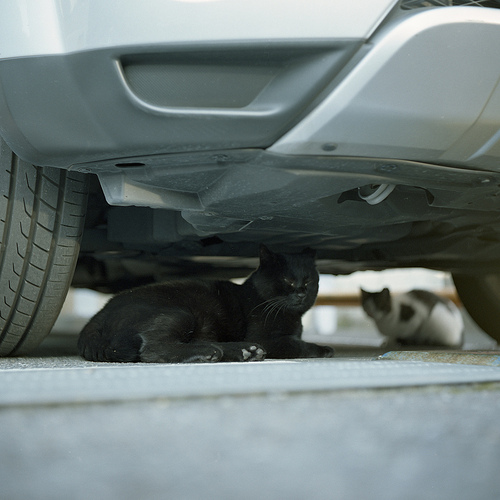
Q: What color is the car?
A: Gray.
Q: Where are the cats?
A: Under the car.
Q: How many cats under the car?
A: Two.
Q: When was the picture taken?
A: In the day.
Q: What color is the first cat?
A: Black.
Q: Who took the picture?
A: Owner of the car.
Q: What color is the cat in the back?
A: White and black.